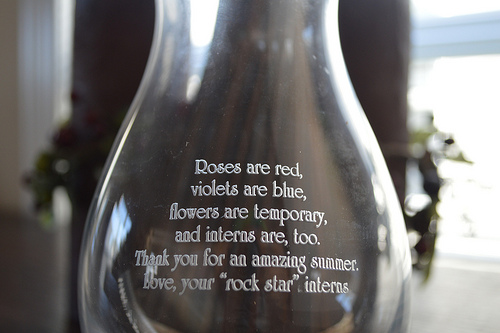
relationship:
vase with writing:
[72, 3, 416, 328] [135, 157, 357, 297]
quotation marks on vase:
[216, 270, 231, 279] [72, 3, 416, 328]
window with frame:
[404, 54, 499, 269] [403, 9, 498, 292]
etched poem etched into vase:
[126, 154, 368, 307] [72, 3, 416, 328]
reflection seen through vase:
[187, 3, 220, 95] [72, 3, 416, 328]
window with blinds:
[20, 8, 77, 231] [2, 3, 73, 231]